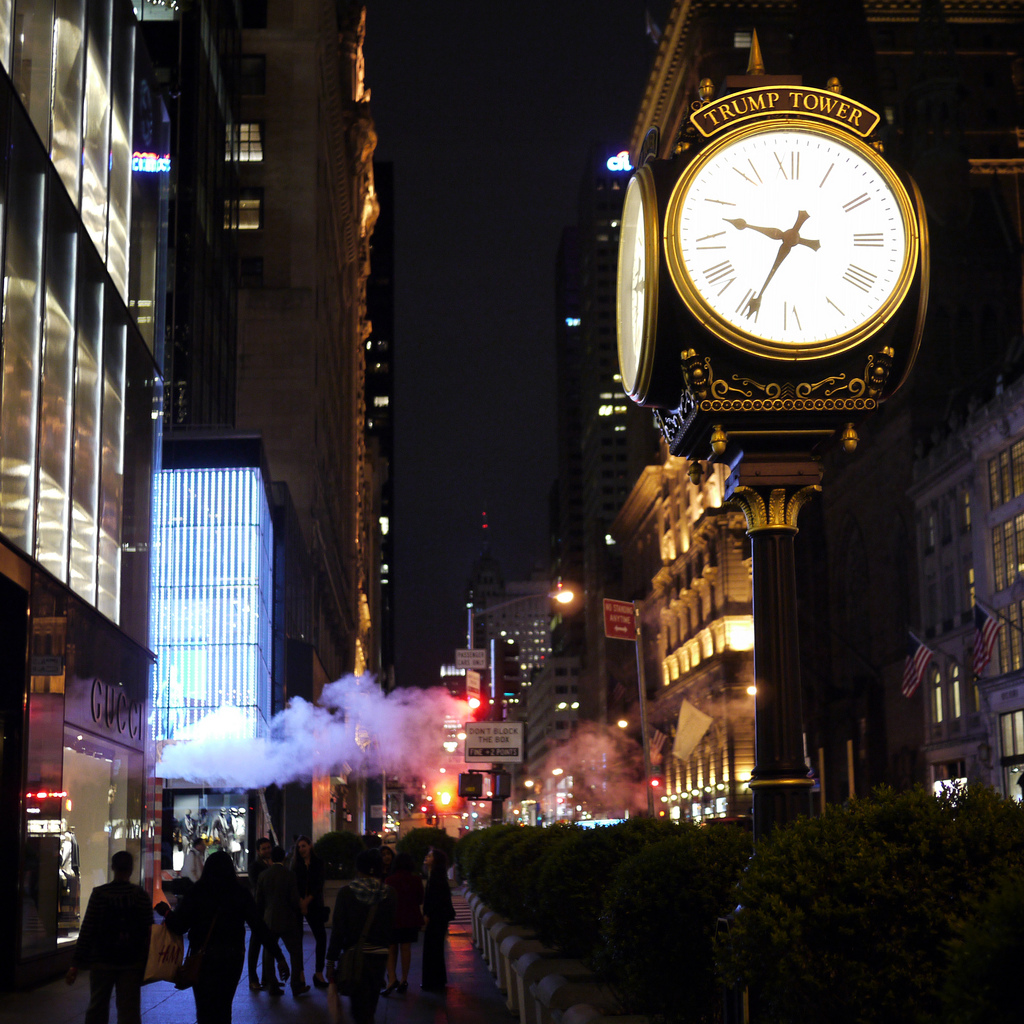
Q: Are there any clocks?
A: Yes, there is a clock.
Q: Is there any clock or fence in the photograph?
A: Yes, there is a clock.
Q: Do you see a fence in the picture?
A: No, there are no fences.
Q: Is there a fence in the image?
A: No, there are no fences.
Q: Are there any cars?
A: No, there are no cars.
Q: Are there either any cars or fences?
A: No, there are no cars or fences.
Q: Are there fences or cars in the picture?
A: No, there are no cars or fences.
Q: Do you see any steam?
A: Yes, there is steam.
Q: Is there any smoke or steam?
A: Yes, there is steam.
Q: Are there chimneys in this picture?
A: No, there are no chimneys.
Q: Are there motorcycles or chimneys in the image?
A: No, there are no chimneys or motorcycles.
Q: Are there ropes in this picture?
A: No, there are no ropes.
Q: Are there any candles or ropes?
A: No, there are no ropes or candles.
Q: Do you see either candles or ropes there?
A: No, there are no ropes or candles.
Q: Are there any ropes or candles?
A: No, there are no ropes or candles.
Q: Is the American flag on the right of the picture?
A: Yes, the American flag is on the right of the image.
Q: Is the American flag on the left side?
A: No, the American flag is on the right of the image.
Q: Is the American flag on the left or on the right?
A: The American flag is on the right of the image.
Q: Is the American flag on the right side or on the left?
A: The American flag is on the right of the image.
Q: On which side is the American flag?
A: The American flag is on the right of the image.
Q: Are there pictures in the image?
A: No, there are no pictures.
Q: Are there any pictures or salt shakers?
A: No, there are no pictures or salt shakers.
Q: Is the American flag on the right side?
A: Yes, the American flag is on the right of the image.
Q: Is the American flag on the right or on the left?
A: The American flag is on the right of the image.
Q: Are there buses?
A: No, there are no buses.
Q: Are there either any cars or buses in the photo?
A: No, there are no buses or cars.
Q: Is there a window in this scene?
A: Yes, there is a window.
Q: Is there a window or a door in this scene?
A: Yes, there is a window.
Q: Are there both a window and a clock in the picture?
A: Yes, there are both a window and a clock.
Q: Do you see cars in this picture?
A: No, there are no cars.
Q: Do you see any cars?
A: No, there are no cars.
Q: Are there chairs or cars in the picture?
A: No, there are no cars or chairs.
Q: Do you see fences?
A: No, there are no fences.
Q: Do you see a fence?
A: No, there are no fences.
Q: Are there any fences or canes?
A: No, there are no fences or canes.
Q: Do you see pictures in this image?
A: No, there are no pictures.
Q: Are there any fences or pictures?
A: No, there are no pictures or fences.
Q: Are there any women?
A: Yes, there is a woman.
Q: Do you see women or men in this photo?
A: Yes, there is a woman.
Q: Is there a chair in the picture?
A: No, there are no chairs.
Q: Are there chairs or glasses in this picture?
A: No, there are no chairs or glasses.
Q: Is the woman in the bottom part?
A: Yes, the woman is in the bottom of the image.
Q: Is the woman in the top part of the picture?
A: No, the woman is in the bottom of the image.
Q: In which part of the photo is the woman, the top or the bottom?
A: The woman is in the bottom of the image.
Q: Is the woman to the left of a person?
A: Yes, the woman is to the left of a person.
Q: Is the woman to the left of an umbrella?
A: No, the woman is to the left of a person.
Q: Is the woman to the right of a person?
A: No, the woman is to the left of a person.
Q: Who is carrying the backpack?
A: The woman is carrying the backpack.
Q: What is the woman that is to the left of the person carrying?
A: The woman is carrying a backpack.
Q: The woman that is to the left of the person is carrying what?
A: The woman is carrying a backpack.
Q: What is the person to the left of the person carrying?
A: The woman is carrying a backpack.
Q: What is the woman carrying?
A: The woman is carrying a backpack.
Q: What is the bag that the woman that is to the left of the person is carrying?
A: The bag is a backpack.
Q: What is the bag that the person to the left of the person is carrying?
A: The bag is a backpack.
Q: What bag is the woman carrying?
A: The woman is carrying a backpack.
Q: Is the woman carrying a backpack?
A: Yes, the woman is carrying a backpack.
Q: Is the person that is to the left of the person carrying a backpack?
A: Yes, the woman is carrying a backpack.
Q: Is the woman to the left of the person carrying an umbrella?
A: No, the woman is carrying a backpack.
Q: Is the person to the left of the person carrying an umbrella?
A: No, the woman is carrying a backpack.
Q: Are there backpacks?
A: Yes, there is a backpack.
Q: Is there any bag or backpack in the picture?
A: Yes, there is a backpack.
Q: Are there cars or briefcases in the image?
A: No, there are no cars or briefcases.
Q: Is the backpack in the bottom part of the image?
A: Yes, the backpack is in the bottom of the image.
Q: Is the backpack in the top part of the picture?
A: No, the backpack is in the bottom of the image.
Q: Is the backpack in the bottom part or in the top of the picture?
A: The backpack is in the bottom of the image.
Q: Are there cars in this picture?
A: No, there are no cars.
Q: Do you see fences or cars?
A: No, there are no cars or fences.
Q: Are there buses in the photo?
A: No, there are no buses.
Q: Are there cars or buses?
A: No, there are no buses or cars.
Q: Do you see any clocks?
A: Yes, there is a clock.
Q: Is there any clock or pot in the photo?
A: Yes, there is a clock.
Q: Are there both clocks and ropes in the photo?
A: No, there is a clock but no ropes.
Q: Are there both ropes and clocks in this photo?
A: No, there is a clock but no ropes.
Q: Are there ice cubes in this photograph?
A: No, there are no ice cubes.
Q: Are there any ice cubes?
A: No, there are no ice cubes.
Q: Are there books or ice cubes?
A: No, there are no ice cubes or books.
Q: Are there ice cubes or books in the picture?
A: No, there are no ice cubes or books.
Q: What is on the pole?
A: The clock is on the pole.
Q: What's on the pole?
A: The clock is on the pole.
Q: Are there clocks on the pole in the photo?
A: Yes, there is a clock on the pole.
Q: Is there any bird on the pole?
A: No, there is a clock on the pole.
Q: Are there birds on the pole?
A: No, there is a clock on the pole.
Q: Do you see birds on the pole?
A: No, there is a clock on the pole.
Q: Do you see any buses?
A: No, there are no buses.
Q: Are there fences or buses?
A: No, there are no buses or fences.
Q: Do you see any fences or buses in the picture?
A: No, there are no buses or fences.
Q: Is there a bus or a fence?
A: No, there are no buses or fences.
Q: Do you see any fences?
A: No, there are no fences.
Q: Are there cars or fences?
A: No, there are no fences or cars.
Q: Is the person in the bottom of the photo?
A: Yes, the person is in the bottom of the image.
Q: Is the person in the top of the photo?
A: No, the person is in the bottom of the image.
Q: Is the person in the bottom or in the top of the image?
A: The person is in the bottom of the image.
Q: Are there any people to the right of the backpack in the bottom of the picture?
A: Yes, there is a person to the right of the backpack.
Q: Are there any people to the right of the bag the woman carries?
A: Yes, there is a person to the right of the backpack.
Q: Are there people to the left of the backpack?
A: No, the person is to the right of the backpack.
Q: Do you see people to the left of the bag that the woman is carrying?
A: No, the person is to the right of the backpack.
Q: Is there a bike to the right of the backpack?
A: No, there is a person to the right of the backpack.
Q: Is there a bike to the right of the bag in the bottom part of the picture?
A: No, there is a person to the right of the backpack.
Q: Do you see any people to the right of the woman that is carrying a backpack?
A: Yes, there is a person to the right of the woman.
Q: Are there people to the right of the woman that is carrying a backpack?
A: Yes, there is a person to the right of the woman.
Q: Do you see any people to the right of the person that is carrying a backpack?
A: Yes, there is a person to the right of the woman.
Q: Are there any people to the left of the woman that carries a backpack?
A: No, the person is to the right of the woman.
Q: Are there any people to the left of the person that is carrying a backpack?
A: No, the person is to the right of the woman.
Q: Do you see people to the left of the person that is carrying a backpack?
A: No, the person is to the right of the woman.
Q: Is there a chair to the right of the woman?
A: No, there is a person to the right of the woman.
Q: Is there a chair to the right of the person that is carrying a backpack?
A: No, there is a person to the right of the woman.